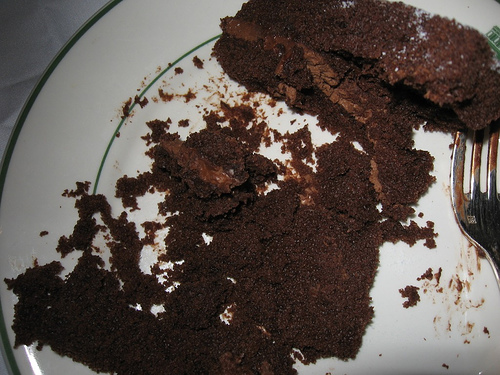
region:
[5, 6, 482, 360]
brownie is caked on plate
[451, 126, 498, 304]
a silver fork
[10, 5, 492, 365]
a white plate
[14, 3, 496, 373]
brown cake on a plate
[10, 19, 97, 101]
creases in a tablecloth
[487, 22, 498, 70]
a green image on a white plate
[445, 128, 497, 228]
brownie on a fork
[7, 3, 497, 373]
a white and green plate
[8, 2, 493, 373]
cake crusted on a plate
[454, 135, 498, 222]
cake crusted on fork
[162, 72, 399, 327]
chocolate cake on the plate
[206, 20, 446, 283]
chocolate cake on the plate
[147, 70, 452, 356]
chocolate cake on the plate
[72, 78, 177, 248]
green line on the plate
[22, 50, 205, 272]
green line on the plate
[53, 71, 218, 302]
green line on the plate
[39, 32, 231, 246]
green line on the plate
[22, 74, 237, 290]
green line on the plate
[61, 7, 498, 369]
a chocolate cake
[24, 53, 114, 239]
part of a white plate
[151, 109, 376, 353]
a spongy chocolate cake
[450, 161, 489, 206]
the light reflected on the fork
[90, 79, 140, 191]
a green curved line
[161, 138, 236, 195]
a tasty chocolate cream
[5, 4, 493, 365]
the chocolate cake is on the plate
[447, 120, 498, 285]
a portion of a fork with cake on it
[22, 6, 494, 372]
chocolate cake smeared all over a plate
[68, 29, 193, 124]
white plate with green accent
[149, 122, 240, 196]
chocolate frosting on the plate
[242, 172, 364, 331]
the cake looks moist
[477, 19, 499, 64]
a green design in the corner of the plate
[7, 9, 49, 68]
white tablecloth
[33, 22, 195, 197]
round plate is holding the cake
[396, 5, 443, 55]
some white powder can be seen on the dessert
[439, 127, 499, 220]
fork is highlighted from the left side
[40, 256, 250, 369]
cake smashed on plate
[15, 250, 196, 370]
chocolate cake smashed on plate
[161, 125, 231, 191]
chocolate filling in cake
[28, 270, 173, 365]
chocolate cake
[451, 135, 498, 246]
silver fork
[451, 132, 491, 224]
fork prongs with chocolate on it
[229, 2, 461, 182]
piece of cake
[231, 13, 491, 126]
piece of chocolate cake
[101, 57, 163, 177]
green marking on plate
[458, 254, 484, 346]
chocolate smear